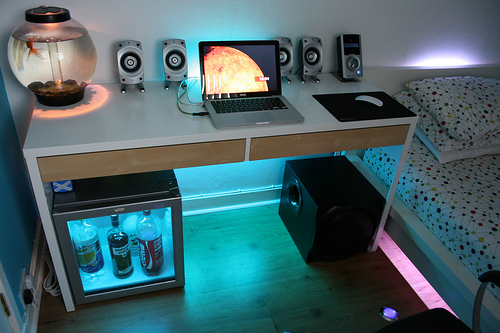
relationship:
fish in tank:
[22, 37, 45, 60] [6, 6, 98, 107]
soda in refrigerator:
[136, 209, 164, 277] [53, 171, 184, 307]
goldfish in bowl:
[22, 37, 45, 60] [6, 6, 98, 107]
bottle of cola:
[136, 209, 164, 277] [139, 242, 148, 266]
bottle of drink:
[107, 212, 134, 280] [109, 237, 128, 245]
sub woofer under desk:
[277, 155, 385, 264] [22, 70, 422, 314]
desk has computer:
[22, 70, 422, 314] [199, 41, 307, 129]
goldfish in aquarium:
[22, 37, 45, 60] [6, 6, 98, 107]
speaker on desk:
[162, 37, 191, 93] [22, 70, 422, 314]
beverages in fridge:
[72, 209, 170, 280] [53, 171, 184, 307]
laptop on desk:
[199, 41, 307, 129] [22, 70, 422, 314]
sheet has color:
[368, 145, 500, 261] [432, 92, 437, 96]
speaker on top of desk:
[115, 41, 145, 94] [22, 70, 422, 314]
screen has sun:
[201, 44, 278, 94] [206, 48, 269, 93]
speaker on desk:
[275, 38, 293, 84] [22, 70, 422, 314]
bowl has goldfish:
[6, 6, 98, 107] [22, 37, 45, 60]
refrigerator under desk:
[53, 171, 184, 307] [22, 70, 422, 314]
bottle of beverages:
[70, 220, 106, 281] [70, 218, 105, 280]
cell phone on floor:
[379, 305, 397, 323] [187, 238, 413, 333]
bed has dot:
[366, 75, 498, 328] [435, 206, 441, 212]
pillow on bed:
[409, 77, 499, 144] [366, 75, 498, 328]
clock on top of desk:
[337, 32, 365, 84] [22, 70, 422, 314]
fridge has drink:
[53, 171, 184, 307] [109, 237, 128, 245]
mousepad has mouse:
[311, 90, 417, 122] [353, 89, 384, 108]